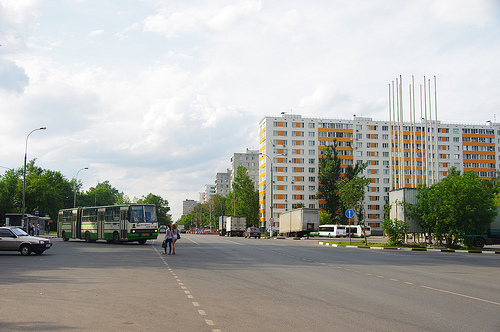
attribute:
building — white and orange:
[271, 114, 442, 235]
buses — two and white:
[322, 224, 375, 247]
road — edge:
[49, 247, 208, 329]